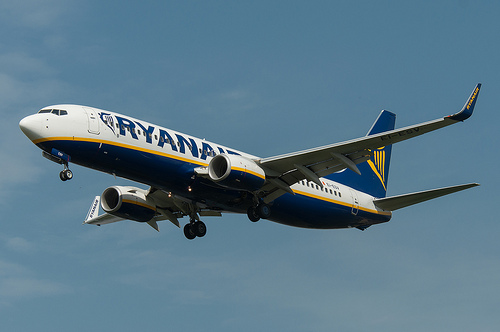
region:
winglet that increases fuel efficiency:
[456, 81, 482, 120]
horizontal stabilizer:
[372, 179, 482, 209]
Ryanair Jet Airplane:
[17, 79, 484, 241]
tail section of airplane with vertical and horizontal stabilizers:
[339, 102, 482, 230]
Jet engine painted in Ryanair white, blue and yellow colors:
[208, 150, 269, 189]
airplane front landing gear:
[57, 156, 72, 182]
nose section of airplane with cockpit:
[17, 103, 71, 180]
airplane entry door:
[85, 109, 100, 134]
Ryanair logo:
[99, 109, 114, 132]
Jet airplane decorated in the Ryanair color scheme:
[17, 79, 486, 239]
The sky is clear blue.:
[7, 7, 497, 306]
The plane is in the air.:
[8, 84, 489, 284]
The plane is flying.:
[15, 51, 487, 303]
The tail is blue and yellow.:
[335, 99, 395, 190]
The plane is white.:
[14, 86, 499, 231]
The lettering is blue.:
[102, 103, 244, 169]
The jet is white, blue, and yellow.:
[204, 152, 274, 187]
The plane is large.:
[20, 92, 492, 249]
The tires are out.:
[158, 214, 208, 242]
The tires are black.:
[176, 214, 210, 246]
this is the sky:
[219, 22, 321, 109]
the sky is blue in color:
[233, 228, 269, 265]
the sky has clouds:
[13, 238, 296, 302]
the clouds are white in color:
[11, 228, 86, 300]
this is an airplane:
[16, 75, 482, 263]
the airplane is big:
[11, 65, 486, 266]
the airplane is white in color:
[46, 117, 68, 131]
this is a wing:
[255, 88, 485, 177]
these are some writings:
[111, 109, 216, 164]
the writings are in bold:
[108, 106, 225, 180]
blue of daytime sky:
[7, 2, 499, 325]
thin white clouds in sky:
[2, 2, 237, 328]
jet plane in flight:
[19, 79, 484, 239]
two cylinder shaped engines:
[99, 154, 264, 224]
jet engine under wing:
[208, 83, 483, 196]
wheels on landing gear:
[171, 187, 211, 240]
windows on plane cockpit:
[38, 104, 67, 118]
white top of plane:
[18, 102, 394, 228]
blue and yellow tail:
[332, 109, 399, 194]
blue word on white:
[112, 112, 242, 169]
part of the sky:
[288, 11, 342, 81]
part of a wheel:
[200, 226, 212, 245]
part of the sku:
[256, 275, 289, 320]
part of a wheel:
[234, 192, 291, 229]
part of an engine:
[221, 123, 237, 168]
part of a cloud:
[273, 272, 307, 322]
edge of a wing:
[271, 135, 295, 171]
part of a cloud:
[323, 240, 344, 266]